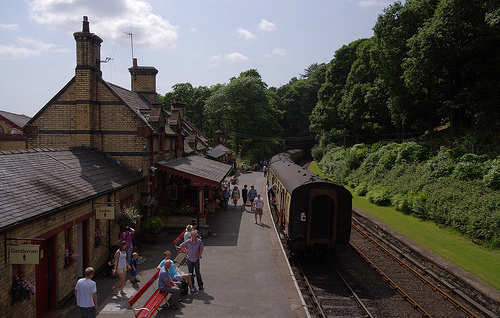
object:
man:
[74, 265, 100, 318]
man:
[253, 193, 265, 225]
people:
[231, 185, 240, 209]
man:
[179, 230, 204, 291]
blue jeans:
[187, 258, 204, 287]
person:
[156, 249, 200, 295]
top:
[268, 147, 354, 197]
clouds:
[125, 7, 139, 17]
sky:
[0, 0, 405, 118]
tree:
[201, 66, 288, 169]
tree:
[158, 79, 207, 132]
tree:
[276, 74, 319, 154]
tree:
[308, 37, 372, 163]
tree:
[384, 0, 500, 138]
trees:
[366, 0, 449, 141]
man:
[156, 258, 181, 311]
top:
[157, 265, 171, 289]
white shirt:
[74, 275, 100, 308]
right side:
[266, 167, 292, 241]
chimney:
[72, 14, 103, 78]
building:
[18, 14, 198, 177]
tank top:
[117, 249, 127, 269]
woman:
[110, 239, 132, 295]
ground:
[63, 147, 500, 318]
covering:
[154, 153, 234, 183]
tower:
[71, 14, 105, 76]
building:
[0, 144, 148, 318]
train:
[265, 147, 355, 253]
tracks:
[408, 254, 438, 278]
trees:
[335, 38, 391, 137]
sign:
[95, 205, 116, 219]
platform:
[61, 169, 308, 318]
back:
[285, 180, 355, 252]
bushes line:
[316, 141, 500, 250]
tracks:
[439, 288, 482, 318]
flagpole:
[129, 33, 134, 58]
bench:
[126, 267, 181, 316]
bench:
[172, 228, 203, 254]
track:
[354, 209, 500, 305]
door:
[310, 193, 336, 239]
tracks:
[382, 275, 431, 318]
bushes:
[366, 140, 430, 206]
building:
[126, 57, 234, 167]